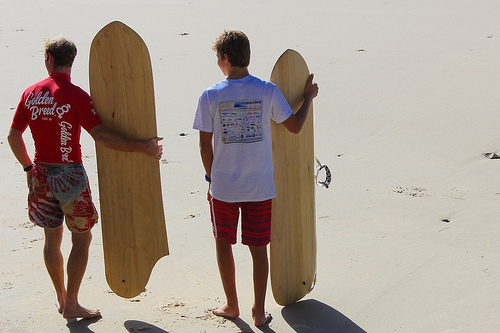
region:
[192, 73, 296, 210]
man wearing a white tshirt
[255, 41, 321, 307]
a wooden makeshift surfboard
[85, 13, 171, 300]
an uneven makeshirt surfboard made of wood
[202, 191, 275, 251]
man wearing red shorts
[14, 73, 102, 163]
man wearing a red shirt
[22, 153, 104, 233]
man wearing red patterned shorts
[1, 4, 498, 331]
sand is very white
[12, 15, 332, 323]
two men standing with their wooden surfboards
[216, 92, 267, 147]
design on man's white tshirt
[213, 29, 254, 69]
man has short brown hair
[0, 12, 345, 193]
two people on the beach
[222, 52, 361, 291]
brown board in man's hand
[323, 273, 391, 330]
shadow on the ground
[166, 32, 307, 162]
white shirt on the person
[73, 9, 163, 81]
front of the board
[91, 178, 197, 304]
back of the board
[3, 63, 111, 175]
red and white shirt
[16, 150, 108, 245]
shorts on the man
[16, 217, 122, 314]
legs of the man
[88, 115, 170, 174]
arm of the man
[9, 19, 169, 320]
A man holding a surfboard.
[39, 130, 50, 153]
Part of a red shirt.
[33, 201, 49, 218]
Part of the man's pants.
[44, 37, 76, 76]
The head of the man.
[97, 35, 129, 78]
Part of the surfboard.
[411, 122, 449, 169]
Part of the sand.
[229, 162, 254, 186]
Part of a white shirt.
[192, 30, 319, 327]
A man holding a surfboard.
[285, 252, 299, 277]
Part of the surfboard.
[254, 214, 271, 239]
Part of the man's pants.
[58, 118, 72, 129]
white letter on shirt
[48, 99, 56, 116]
white letter on shirt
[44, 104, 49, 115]
white letter on shirt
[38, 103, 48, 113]
white letter on shirt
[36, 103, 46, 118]
white letter on shirt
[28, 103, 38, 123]
white letter on shirt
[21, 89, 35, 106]
white letter on shirt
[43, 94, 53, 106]
white letter on shirt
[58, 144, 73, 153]
white letter on shirt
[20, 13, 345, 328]
boys holding wooden surfboards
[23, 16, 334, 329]
boys holding wooden surfboards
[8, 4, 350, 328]
boys holding wooden surfboards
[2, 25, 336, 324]
boys holding wooden surfboards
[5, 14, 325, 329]
boys holding wooden surfboards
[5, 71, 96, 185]
the top is red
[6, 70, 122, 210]
the top is red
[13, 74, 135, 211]
the top is red